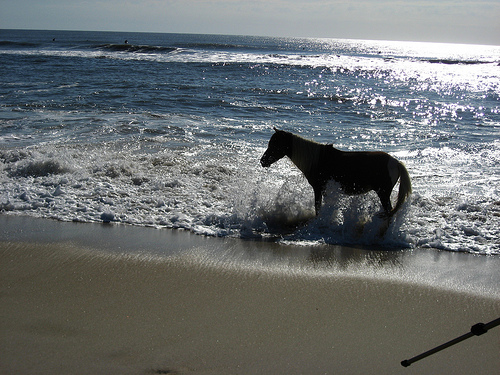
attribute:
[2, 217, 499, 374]
sand — black, beach, saturated, shore, tan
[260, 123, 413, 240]
horse — wet, splashing, walking, dark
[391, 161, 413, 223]
tail — long, swishing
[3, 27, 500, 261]
ocean — blue, rocky, splashing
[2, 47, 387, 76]
wave — white, crashing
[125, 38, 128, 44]
bird — sitting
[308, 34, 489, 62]
reflection — sun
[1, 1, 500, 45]
sky — mild, clear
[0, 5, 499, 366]
beach — day, blue, white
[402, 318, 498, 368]
shadow — dark